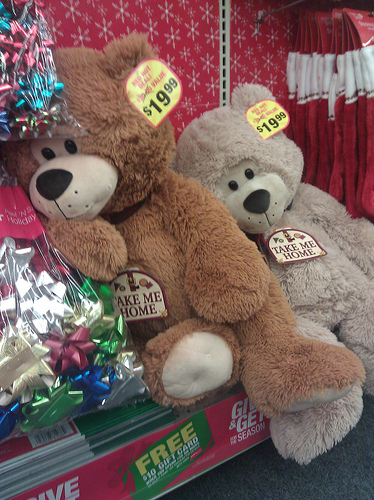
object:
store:
[0, 4, 374, 500]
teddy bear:
[165, 83, 373, 463]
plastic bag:
[3, 160, 149, 442]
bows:
[0, 18, 69, 83]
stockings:
[283, 7, 372, 222]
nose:
[36, 168, 73, 200]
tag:
[237, 96, 298, 145]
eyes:
[40, 81, 78, 101]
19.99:
[253, 111, 293, 142]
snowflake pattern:
[39, 4, 292, 134]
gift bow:
[0, 273, 148, 436]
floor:
[186, 393, 372, 497]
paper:
[39, 3, 298, 144]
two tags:
[125, 63, 291, 141]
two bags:
[3, 28, 374, 452]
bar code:
[31, 420, 69, 448]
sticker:
[124, 408, 222, 496]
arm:
[151, 173, 269, 327]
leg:
[211, 248, 361, 412]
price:
[136, 77, 178, 120]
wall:
[2, 4, 360, 169]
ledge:
[14, 384, 297, 497]